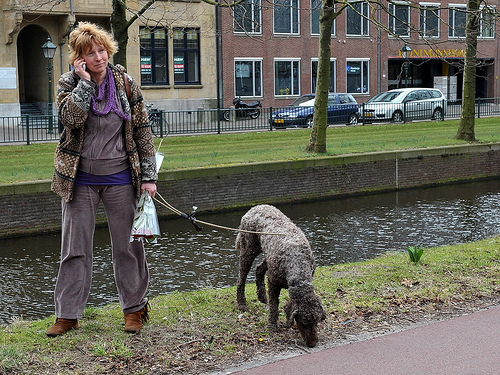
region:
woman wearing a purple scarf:
[17, 5, 184, 328]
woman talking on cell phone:
[6, 15, 192, 228]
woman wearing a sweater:
[47, 12, 174, 258]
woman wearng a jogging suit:
[40, 13, 208, 354]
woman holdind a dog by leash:
[43, 25, 349, 347]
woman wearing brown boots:
[10, 22, 177, 355]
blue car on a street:
[271, 92, 312, 122]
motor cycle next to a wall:
[223, 83, 263, 128]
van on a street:
[357, 65, 447, 122]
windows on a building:
[135, 12, 219, 103]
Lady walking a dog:
[43, 18, 154, 338]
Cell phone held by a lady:
[72, 55, 90, 73]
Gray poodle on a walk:
[228, 205, 328, 346]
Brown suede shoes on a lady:
[120, 305, 146, 335]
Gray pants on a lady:
[55, 180, 150, 318]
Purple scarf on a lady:
[83, 65, 124, 116]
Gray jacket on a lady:
[76, 96, 128, 173]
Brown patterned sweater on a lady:
[47, 61, 154, 199]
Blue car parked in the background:
[267, 90, 358, 130]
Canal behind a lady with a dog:
[1, 175, 498, 324]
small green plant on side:
[396, 234, 431, 266]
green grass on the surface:
[338, 266, 399, 295]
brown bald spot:
[148, 318, 240, 360]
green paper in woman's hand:
[120, 179, 181, 270]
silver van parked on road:
[373, 82, 450, 132]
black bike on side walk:
[219, 91, 276, 122]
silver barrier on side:
[173, 92, 293, 139]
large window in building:
[134, 16, 224, 103]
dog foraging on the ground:
[235, 201, 334, 340]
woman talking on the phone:
[47, 17, 160, 199]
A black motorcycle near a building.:
[222, 95, 262, 120]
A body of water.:
[0, 175, 498, 328]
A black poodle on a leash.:
[235, 203, 328, 348]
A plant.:
[405, 243, 425, 263]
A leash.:
[151, 188, 313, 288]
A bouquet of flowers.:
[125, 136, 166, 242]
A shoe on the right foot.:
[45, 314, 78, 334]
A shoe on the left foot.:
[121, 304, 149, 332]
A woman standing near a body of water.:
[45, 19, 157, 334]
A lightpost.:
[41, 36, 55, 133]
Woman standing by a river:
[45, 18, 157, 336]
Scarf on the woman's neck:
[89, 66, 127, 122]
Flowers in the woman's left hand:
[128, 137, 165, 244]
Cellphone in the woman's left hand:
[74, 58, 87, 69]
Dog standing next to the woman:
[236, 205, 326, 347]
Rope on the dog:
[150, 190, 293, 239]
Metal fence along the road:
[1, 97, 495, 142]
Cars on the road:
[270, 83, 447, 126]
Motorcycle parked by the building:
[225, 92, 263, 119]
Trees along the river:
[14, 0, 494, 150]